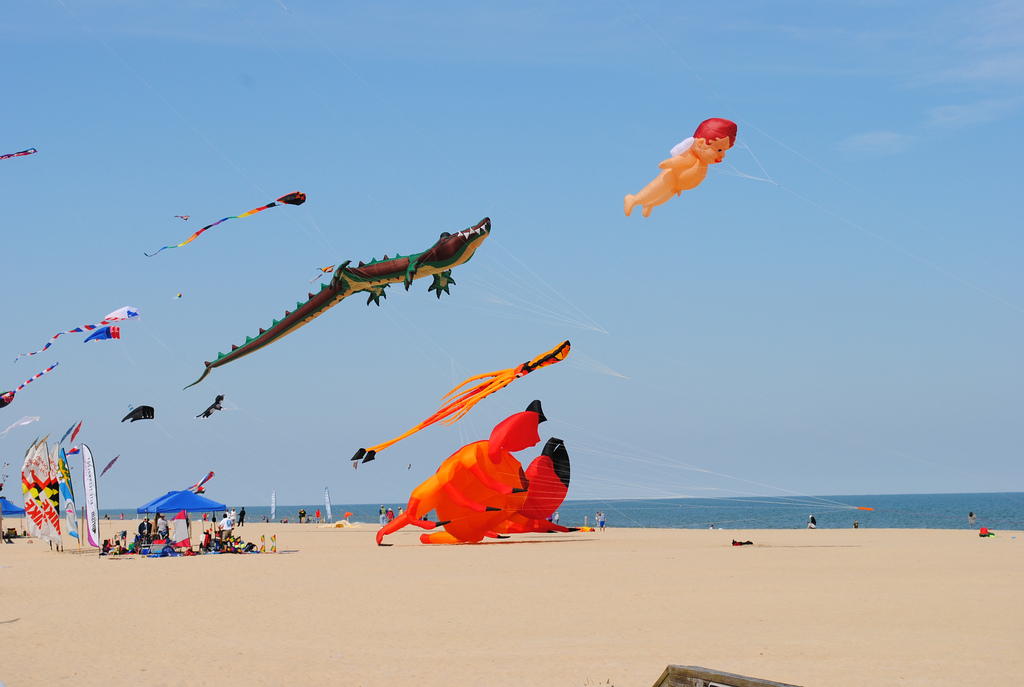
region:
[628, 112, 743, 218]
A kite shaped like a baby in the air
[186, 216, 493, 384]
A crocodile shaped kite in the air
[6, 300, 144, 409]
Two colorful kites in the air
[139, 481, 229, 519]
A blue tent on the beach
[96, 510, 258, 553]
People sitting on the beach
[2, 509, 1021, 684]
Sand at the beach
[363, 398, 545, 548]
An orange kite in the sand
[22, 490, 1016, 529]
Water in the ocean at the beach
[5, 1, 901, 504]
Blue sky over the beach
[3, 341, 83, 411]
A tail on a kite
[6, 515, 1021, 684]
tan sand in front of water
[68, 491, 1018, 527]
blue body of water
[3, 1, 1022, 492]
blue sky with light white clouds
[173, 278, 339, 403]
aligator tail of kite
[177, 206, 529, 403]
kite made to look like aligator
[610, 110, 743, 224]
angel kite with wings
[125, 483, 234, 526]
blue tent covering on sand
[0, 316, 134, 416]
red and blue kite in the sky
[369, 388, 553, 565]
orange kite on the sand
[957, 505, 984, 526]
person with dark hair in the water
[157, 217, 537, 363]
A balloon allegator in the sky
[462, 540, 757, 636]
Brown sand on the beach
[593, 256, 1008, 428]
A blue sky without clouds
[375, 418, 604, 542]
A orange item on the beach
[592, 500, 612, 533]
A person standing by the balloon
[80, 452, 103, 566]
A tall flag standing on the beach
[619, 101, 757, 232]
a kite that is a baby doll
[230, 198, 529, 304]
a kite that is a dragon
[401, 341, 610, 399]
a kite that is orange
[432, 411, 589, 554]
a kite that is red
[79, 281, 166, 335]
a kite that is white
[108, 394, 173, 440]
a kite that is black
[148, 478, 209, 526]
an umbrella that is blue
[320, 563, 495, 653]
the sand is brown in color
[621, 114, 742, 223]
A kite shaped like a child in the air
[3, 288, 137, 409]
Colorful kites in the air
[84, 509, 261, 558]
People under a tent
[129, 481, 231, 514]
A blue tent at the beach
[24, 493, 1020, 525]
Water near a beach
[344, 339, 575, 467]
An orange kite in the air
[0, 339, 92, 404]
The tail on a kite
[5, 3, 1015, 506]
Blue sky over a beach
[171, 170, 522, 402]
kite shape like a croc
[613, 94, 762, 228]
a baby shaped kite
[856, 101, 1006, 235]
Large body of blue skies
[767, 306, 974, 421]
Large body of blue skies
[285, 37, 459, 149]
Large body of blue skies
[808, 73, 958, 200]
Large body of blue skies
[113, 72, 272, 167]
Large body of blue skies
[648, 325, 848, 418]
Large body of blue skies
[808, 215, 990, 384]
Large body of blue skies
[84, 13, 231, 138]
Large body of blue skies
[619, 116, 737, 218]
red hair on kite shaped like a child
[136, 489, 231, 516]
blue cover on a pavilion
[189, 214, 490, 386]
brown and green alligator balloon kite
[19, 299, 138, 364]
red white and blue kite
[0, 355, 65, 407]
red white and blue kite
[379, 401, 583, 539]
large red balloon lying on the beach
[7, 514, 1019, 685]
tan sand on beach by the water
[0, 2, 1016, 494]
clear blue sky with few wispy clouds